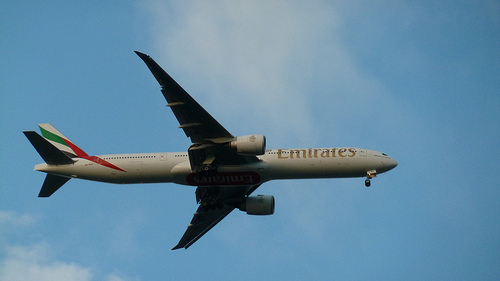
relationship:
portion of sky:
[413, 19, 484, 97] [10, 9, 485, 266]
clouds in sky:
[125, 14, 378, 138] [10, 9, 485, 266]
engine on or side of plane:
[244, 192, 275, 216] [22, 49, 397, 249]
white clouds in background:
[204, 6, 348, 104] [15, 1, 459, 116]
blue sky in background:
[58, 8, 133, 70] [0, 0, 482, 103]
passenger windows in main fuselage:
[100, 153, 160, 160] [65, 151, 170, 181]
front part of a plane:
[363, 145, 399, 183] [22, 49, 397, 249]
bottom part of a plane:
[80, 162, 398, 240] [22, 49, 397, 249]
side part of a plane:
[280, 149, 375, 163] [22, 49, 397, 249]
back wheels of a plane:
[196, 180, 212, 199] [22, 49, 397, 249]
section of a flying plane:
[190, 165, 245, 186] [19, 47, 398, 252]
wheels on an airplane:
[357, 176, 375, 188] [21, 45, 401, 260]